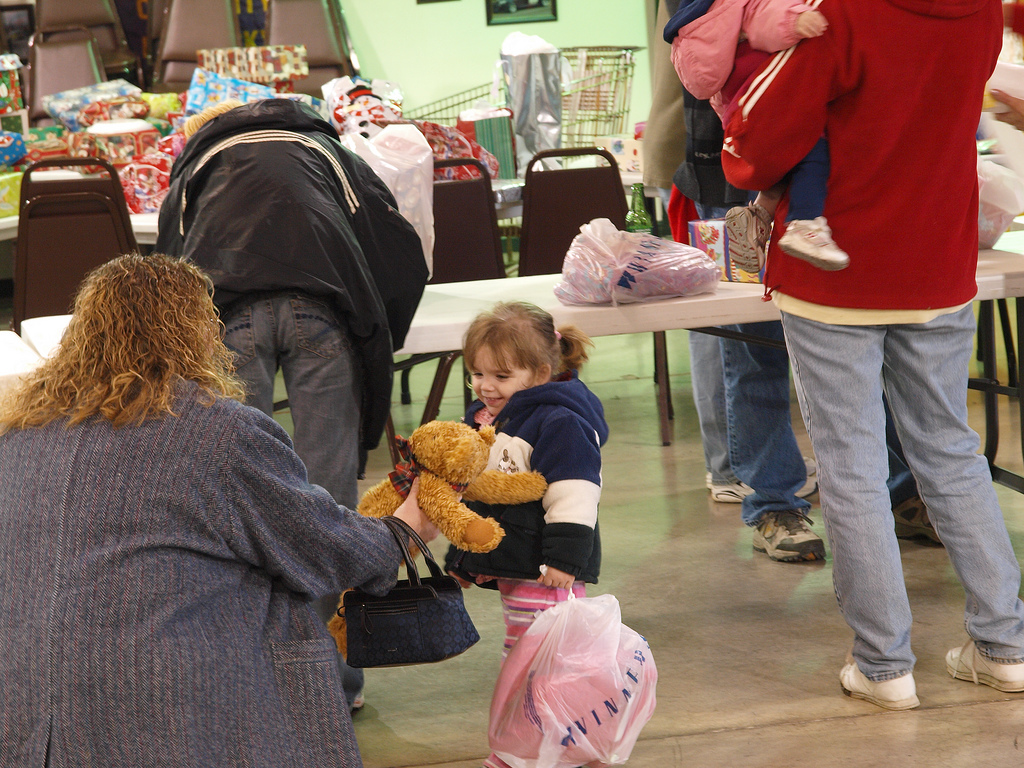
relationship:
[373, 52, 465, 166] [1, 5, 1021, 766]
wall on side of building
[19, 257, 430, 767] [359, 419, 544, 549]
woman showing teddybear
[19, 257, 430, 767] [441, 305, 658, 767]
woman showing girl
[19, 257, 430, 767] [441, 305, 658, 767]
woman showing teddy bear to girl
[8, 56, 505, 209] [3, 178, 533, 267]
presents on table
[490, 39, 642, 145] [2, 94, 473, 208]
cart next to table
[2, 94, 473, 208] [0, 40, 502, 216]
table with presents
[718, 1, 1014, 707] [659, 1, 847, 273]
person holding baby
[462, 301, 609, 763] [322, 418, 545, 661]
girl looking at teddy bear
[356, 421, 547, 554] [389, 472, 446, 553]
toy in hand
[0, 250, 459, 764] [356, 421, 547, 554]
woman holding toy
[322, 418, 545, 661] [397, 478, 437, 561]
teddy bear on hand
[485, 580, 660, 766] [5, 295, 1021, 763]
bag on ground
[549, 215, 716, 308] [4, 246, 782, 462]
bag on table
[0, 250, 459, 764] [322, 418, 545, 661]
woman holding teddy bear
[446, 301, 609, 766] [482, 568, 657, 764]
girl holding bag